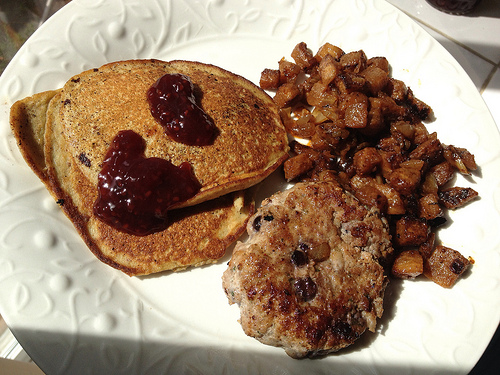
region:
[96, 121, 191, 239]
the red colored jam served to eat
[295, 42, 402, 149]
fried potato curry ready to eat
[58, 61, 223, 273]
brown colored dosa delicious ready toea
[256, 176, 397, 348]
a delicious dosa ready to eat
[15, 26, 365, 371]
a white colored plate serves with food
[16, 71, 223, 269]
three set of dosa ready to eat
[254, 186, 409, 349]
a single dosa roasted ready to eat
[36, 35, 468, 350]
full plate tiffin decorated nicely and ready to eat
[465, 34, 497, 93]
the shadow of a man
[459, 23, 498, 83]
the designed white tiles on the floor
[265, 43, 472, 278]
The hash brown have been cooked.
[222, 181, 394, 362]
Sausage patty is next to hash browns.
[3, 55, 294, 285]
There are two pancakes.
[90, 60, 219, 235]
There's strawberry jam on pancakes.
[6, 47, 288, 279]
Pancakes are next to sausage.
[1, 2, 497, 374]
Food served on a white plate.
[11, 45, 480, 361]
Foods associated with breakfast.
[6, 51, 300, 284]
Pancakes are next to the hash browns.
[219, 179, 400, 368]
Sausage patty has been browned.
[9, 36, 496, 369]
A well balanced breakfast.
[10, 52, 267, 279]
The pancake on the plate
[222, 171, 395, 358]
The sausage on the plate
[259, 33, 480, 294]
The chopped potatoes nect to the sausage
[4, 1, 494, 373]
The plate the food is on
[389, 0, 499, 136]
The white tile the plate is on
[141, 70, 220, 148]
The small dollop of jelly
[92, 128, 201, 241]
The large dollop of jelly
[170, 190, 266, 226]
The shadow of the top pancake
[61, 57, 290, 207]
The pancake of top of the other one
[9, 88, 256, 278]
The pancake below the other one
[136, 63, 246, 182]
a blob of jelly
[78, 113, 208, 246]
a thick red jam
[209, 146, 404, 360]
a misshaped sausage patty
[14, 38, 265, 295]
a short stack of pancakes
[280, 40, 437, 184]
a pile of breakfast potatoes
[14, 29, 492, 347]
a home made breakfast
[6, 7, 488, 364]
a white china plate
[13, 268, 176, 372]
decorative print on plate rim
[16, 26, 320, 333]
pancakes on a white plate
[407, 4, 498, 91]
some white tiles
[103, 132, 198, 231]
A purple-like jam.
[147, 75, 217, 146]
A grape looking type of jelly.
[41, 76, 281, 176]
A darkened piece of toast.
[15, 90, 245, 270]
Another darkened piece of toast.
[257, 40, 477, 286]
Dark, well done hash browns.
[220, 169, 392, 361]
A toasted English muffin.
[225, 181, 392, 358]
A dark brown English muffin.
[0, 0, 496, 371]
A fully white porcelain decorated plate.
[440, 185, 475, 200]
A piece of home fries.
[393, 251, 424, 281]
A roasted piece of potato.